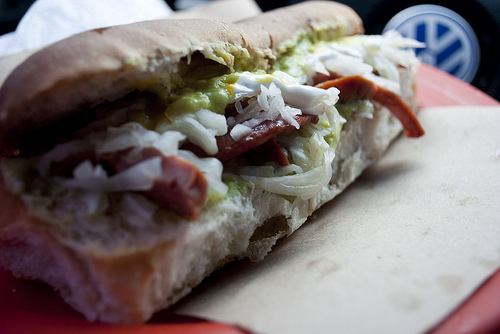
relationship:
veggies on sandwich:
[50, 29, 412, 221] [0, 2, 417, 319]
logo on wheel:
[378, 0, 482, 100] [377, 0, 479, 83]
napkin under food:
[2, 0, 498, 330] [0, 0, 430, 325]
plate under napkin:
[431, 72, 470, 107] [374, 156, 468, 293]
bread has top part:
[1, 0, 415, 326] [0, 6, 366, 77]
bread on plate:
[1, 0, 415, 326] [407, 69, 491, 115]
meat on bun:
[92, 138, 223, 218] [6, 0, 425, 331]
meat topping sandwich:
[212, 103, 315, 178] [0, 2, 417, 319]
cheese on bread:
[129, 122, 224, 149] [9, 11, 198, 96]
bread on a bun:
[1, 0, 415, 326] [13, 19, 366, 215]